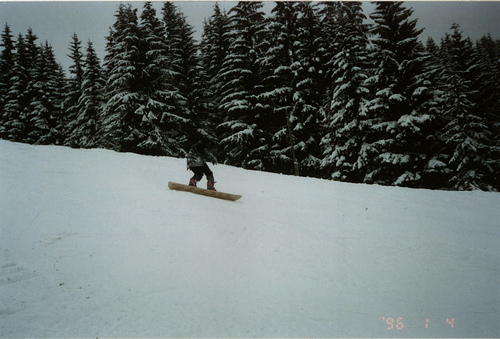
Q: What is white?
A: Snow.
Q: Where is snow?
A: On pine trees.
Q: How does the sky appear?
A: Overcast.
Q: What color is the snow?
A: White.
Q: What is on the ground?
A: Snow.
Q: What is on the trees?
A: Snow.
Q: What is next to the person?
A: Trees.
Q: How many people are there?
A: One.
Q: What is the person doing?
A: Snowboarding.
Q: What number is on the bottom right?
A: 96.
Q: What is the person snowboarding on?
A: A slope.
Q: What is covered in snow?
A: Pine trees.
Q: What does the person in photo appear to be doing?
A: Snowboarding.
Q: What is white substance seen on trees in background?
A: Snow.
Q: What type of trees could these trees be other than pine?
A: Fir.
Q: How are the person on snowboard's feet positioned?
A: Splayed.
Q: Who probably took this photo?
A: Amateur photographer.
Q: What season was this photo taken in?
A: Winter.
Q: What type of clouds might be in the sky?
A: Snow clouds.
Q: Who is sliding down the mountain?
A: Snowboarder.